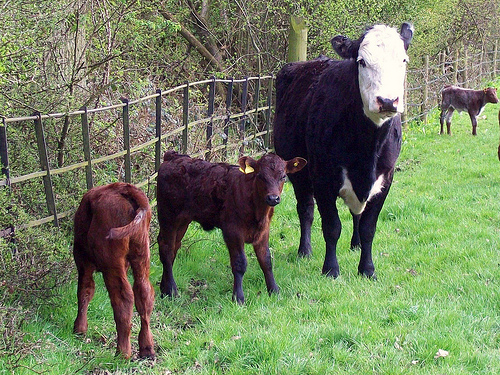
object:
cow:
[271, 22, 414, 281]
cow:
[71, 182, 155, 362]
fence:
[0, 27, 498, 295]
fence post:
[281, 15, 307, 66]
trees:
[1, 1, 498, 197]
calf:
[153, 148, 306, 307]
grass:
[178, 277, 229, 313]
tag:
[243, 163, 257, 174]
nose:
[265, 194, 279, 206]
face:
[355, 27, 408, 118]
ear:
[329, 35, 355, 60]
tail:
[102, 184, 150, 241]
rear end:
[95, 187, 152, 263]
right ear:
[236, 154, 262, 173]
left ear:
[282, 157, 307, 174]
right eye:
[256, 173, 265, 180]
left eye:
[279, 172, 288, 181]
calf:
[437, 86, 497, 136]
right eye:
[356, 56, 368, 69]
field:
[0, 88, 499, 375]